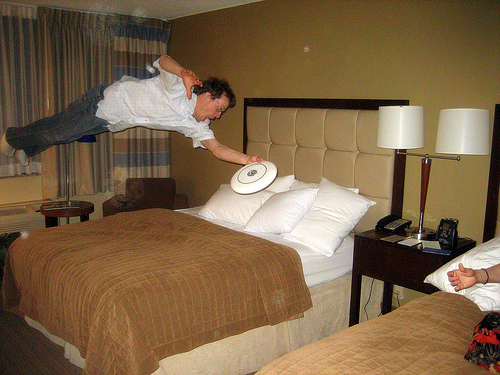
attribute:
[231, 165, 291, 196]
frisbee — white, round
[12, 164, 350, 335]
bed — brown, white, foreground, padded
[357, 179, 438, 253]
telephone — black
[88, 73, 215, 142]
shirt — white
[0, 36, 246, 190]
man — wearing, airborne, holding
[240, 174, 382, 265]
pillow — white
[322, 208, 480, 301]
table — wood, bedside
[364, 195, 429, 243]
phone — black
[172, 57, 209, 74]
wristband — black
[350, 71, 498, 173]
lamp — double, white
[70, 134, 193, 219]
chair — brown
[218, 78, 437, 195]
headboard — beige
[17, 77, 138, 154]
jean — blue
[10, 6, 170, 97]
curtain — brown